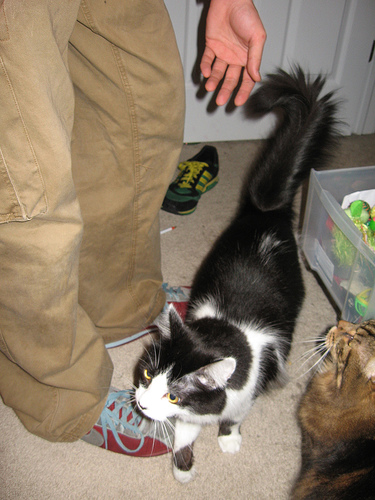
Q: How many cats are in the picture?
A: 2.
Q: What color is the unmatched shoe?
A: Green, black and yellow.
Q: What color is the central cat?
A: Black and white.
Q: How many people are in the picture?
A: 1.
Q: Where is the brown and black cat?
A: Lower right.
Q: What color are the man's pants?
A: Brown.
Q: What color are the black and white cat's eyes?
A: Yellow.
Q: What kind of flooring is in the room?
A: Carpet.